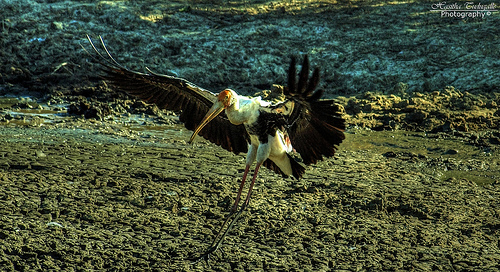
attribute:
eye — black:
[224, 90, 232, 102]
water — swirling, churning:
[30, 89, 492, 166]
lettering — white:
[436, 0, 493, 19]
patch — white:
[230, 89, 267, 125]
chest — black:
[224, 96, 259, 125]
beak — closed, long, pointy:
[183, 100, 226, 146]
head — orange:
[186, 86, 232, 144]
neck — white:
[232, 101, 259, 125]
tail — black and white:
[279, 44, 354, 169]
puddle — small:
[422, 157, 499, 196]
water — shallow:
[6, 93, 84, 130]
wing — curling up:
[80, 35, 247, 164]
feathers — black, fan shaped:
[280, 52, 347, 165]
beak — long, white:
[191, 101, 225, 141]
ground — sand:
[6, 167, 498, 269]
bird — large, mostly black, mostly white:
[71, 30, 365, 268]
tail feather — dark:
[306, 65, 321, 102]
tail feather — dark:
[310, 79, 333, 103]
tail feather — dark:
[296, 53, 308, 101]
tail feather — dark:
[282, 50, 296, 96]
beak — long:
[188, 101, 226, 143]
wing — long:
[87, 36, 245, 158]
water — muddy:
[359, 118, 468, 164]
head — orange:
[219, 87, 239, 113]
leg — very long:
[190, 160, 261, 258]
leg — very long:
[181, 158, 249, 261]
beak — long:
[186, 100, 224, 150]